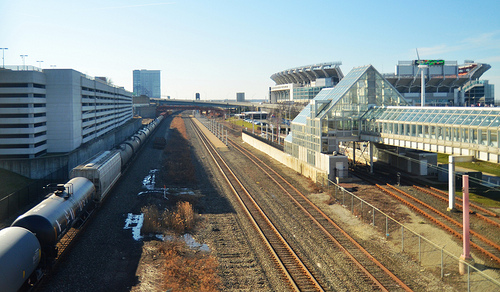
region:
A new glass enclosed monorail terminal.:
[281, 63, 499, 179]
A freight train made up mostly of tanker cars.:
[0, 105, 174, 290]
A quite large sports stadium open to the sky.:
[263, 59, 496, 112]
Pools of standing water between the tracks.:
[124, 165, 211, 257]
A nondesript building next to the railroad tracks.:
[0, 61, 142, 180]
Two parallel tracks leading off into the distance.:
[184, 107, 411, 290]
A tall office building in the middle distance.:
[129, 67, 164, 99]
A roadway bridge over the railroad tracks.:
[150, 95, 296, 115]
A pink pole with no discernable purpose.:
[455, 170, 479, 275]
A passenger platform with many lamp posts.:
[188, 111, 230, 151]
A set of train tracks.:
[228, 173, 313, 277]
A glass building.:
[299, 74, 409, 173]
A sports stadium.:
[266, 54, 488, 119]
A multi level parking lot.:
[3, 66, 137, 158]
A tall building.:
[130, 66, 164, 102]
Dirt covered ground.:
[215, 218, 242, 285]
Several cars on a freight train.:
[91, 113, 163, 204]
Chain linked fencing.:
[333, 191, 399, 222]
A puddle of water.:
[123, 209, 143, 244]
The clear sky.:
[200, 16, 317, 56]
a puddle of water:
[118, 204, 156, 243]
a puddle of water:
[117, 206, 172, 263]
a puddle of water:
[107, 194, 191, 256]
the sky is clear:
[159, 26, 251, 66]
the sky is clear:
[142, 12, 262, 74]